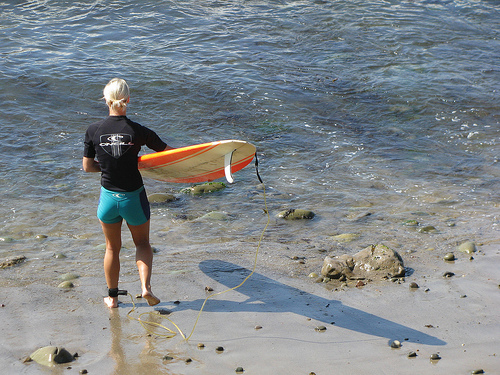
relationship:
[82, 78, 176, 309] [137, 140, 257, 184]
woman holding surfboard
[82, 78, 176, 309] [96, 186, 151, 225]
woman wearing shorts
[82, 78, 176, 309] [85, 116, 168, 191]
woman wearing a top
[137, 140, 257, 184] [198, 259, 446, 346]
surfboard making a shadow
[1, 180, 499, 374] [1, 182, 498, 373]
sand around rocks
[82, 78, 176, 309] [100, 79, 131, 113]
woman has hair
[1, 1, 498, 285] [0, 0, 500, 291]
water has ripples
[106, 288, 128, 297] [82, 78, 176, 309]
object on woman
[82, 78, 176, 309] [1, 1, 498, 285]
woman looking at water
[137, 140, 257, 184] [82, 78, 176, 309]
surfboard attached to woman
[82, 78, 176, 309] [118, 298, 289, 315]
woman has a shadow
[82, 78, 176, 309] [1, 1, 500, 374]
woman at beach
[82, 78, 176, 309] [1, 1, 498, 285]
woman standing near water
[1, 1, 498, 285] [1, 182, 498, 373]
water has rocks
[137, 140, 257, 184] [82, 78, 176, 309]
surfboard held by woman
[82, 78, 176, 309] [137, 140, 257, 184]
woman standing with a surfboard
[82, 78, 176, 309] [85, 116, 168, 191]
woman has a black top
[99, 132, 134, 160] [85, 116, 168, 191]
white on top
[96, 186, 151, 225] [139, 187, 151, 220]
shorts have color black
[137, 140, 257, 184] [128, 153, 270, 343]
surfboard has a cord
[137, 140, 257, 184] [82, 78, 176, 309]
surfboard being carried by woman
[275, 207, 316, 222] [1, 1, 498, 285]
rock in water